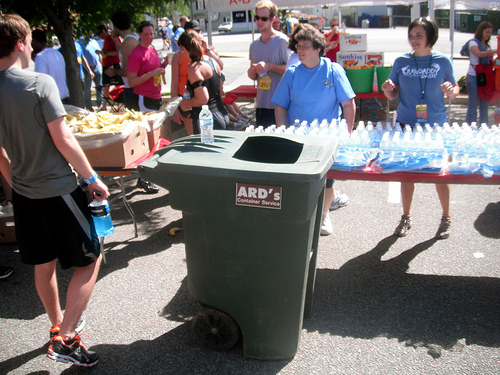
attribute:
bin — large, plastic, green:
[127, 129, 337, 360]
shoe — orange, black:
[46, 336, 100, 367]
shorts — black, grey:
[11, 192, 99, 268]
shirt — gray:
[1, 69, 81, 200]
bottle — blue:
[89, 192, 115, 239]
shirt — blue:
[273, 59, 354, 121]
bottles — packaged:
[337, 117, 499, 171]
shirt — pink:
[128, 44, 164, 100]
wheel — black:
[191, 305, 239, 354]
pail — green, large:
[345, 64, 374, 94]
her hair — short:
[406, 12, 438, 49]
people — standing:
[249, 1, 290, 126]